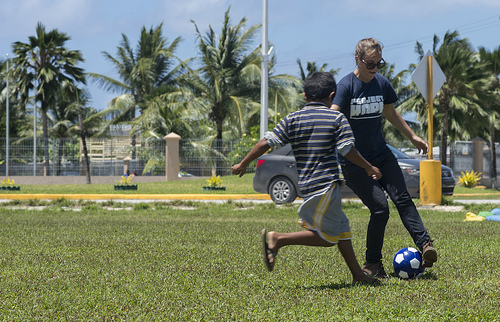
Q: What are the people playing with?
A: A ball.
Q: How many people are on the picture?
A: Two.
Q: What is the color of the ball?
A: White and blue.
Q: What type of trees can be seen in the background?
A: Palm trees.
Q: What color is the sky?
A: Blue.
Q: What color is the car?
A: Grey.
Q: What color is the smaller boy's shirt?
A: Black and white.